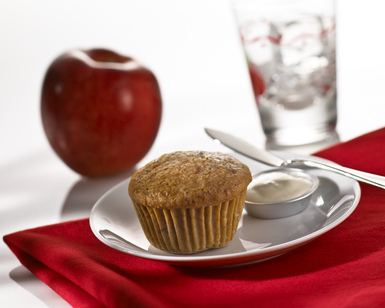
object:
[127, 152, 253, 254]
muffin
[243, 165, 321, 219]
container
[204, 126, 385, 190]
knife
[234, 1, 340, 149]
glass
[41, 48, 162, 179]
apple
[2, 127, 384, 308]
napkin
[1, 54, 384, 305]
table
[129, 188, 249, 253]
wrapper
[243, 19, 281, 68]
ice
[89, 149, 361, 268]
plate